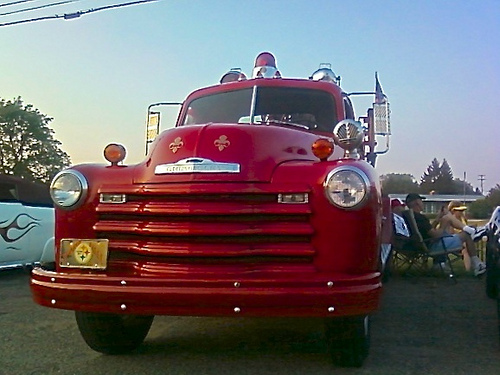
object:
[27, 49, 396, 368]
truck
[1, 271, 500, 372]
pavement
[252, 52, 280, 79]
siren light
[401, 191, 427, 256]
man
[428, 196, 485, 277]
woman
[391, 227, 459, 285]
chair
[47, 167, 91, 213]
headlight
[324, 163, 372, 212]
headlight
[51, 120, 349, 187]
hood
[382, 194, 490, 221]
house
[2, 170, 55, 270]
car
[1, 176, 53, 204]
top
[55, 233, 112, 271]
tag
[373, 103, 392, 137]
mirror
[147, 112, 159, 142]
mirror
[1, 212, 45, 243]
flame design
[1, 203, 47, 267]
car door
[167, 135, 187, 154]
fleurs-de-lis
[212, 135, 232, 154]
fleurs-de-lis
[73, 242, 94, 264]
pittsburgh steelers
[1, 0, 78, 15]
line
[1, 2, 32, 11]
line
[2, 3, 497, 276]
background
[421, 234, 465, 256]
shorts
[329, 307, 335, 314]
stud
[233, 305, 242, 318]
stud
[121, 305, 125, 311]
stud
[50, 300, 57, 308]
stud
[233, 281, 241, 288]
stud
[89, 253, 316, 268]
grove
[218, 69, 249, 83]
light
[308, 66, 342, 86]
light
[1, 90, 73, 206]
tree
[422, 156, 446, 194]
tree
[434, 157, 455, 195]
tree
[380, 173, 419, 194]
tree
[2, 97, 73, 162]
top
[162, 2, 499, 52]
sky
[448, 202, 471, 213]
visor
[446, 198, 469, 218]
woman's head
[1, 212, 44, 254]
design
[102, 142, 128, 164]
light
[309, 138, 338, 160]
light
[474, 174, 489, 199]
electrical pole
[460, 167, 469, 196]
electrical pole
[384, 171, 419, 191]
trees